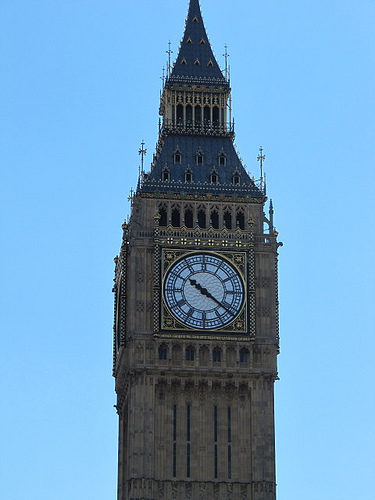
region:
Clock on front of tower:
[146, 233, 271, 340]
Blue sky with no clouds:
[15, 357, 80, 477]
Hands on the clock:
[187, 279, 235, 311]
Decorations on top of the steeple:
[130, 136, 278, 203]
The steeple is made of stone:
[116, 350, 316, 445]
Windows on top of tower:
[157, 133, 250, 191]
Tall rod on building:
[256, 142, 276, 200]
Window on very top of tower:
[190, 11, 201, 25]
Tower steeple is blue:
[169, 7, 243, 85]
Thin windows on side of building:
[170, 398, 239, 476]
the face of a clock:
[160, 250, 244, 330]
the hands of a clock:
[184, 274, 233, 315]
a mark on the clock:
[197, 251, 209, 275]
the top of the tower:
[148, 1, 238, 137]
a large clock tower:
[91, 0, 290, 499]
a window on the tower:
[196, 204, 208, 229]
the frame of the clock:
[160, 243, 250, 334]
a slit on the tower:
[180, 400, 196, 480]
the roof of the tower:
[163, 1, 227, 81]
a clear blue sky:
[0, 0, 373, 499]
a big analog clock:
[153, 237, 259, 340]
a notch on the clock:
[198, 252, 209, 271]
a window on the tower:
[167, 201, 182, 227]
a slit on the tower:
[165, 398, 182, 482]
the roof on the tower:
[165, 0, 228, 81]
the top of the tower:
[115, 0, 270, 233]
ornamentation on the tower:
[133, 133, 149, 181]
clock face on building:
[154, 253, 248, 345]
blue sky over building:
[296, 387, 353, 478]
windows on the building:
[187, 404, 238, 490]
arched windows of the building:
[141, 343, 258, 361]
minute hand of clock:
[195, 290, 235, 322]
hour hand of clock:
[181, 275, 207, 300]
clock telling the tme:
[170, 253, 240, 344]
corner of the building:
[100, 319, 124, 494]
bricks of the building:
[255, 422, 271, 470]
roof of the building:
[141, 139, 249, 195]